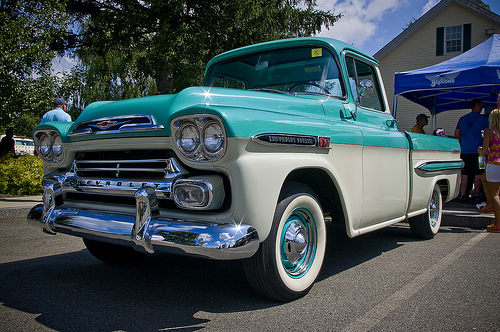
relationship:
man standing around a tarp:
[411, 113, 430, 135] [430, 70, 482, 102]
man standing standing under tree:
[41, 99, 72, 123] [64, 1, 344, 93]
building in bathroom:
[371, 2, 498, 122] [444, 26, 471, 51]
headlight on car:
[175, 116, 225, 158] [27, 37, 462, 299]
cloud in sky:
[325, 5, 357, 35] [284, 2, 479, 67]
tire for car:
[254, 194, 386, 272] [45, 56, 376, 240]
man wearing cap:
[43, 106, 71, 134] [56, 94, 69, 104]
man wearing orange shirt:
[413, 112, 430, 135] [411, 123, 423, 133]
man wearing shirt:
[450, 95, 487, 210] [457, 110, 489, 155]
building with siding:
[371, 2, 499, 149] [368, 1, 492, 137]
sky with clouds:
[366, 1, 431, 56] [313, 4, 430, 46]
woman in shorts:
[476, 106, 498, 231] [482, 159, 499, 184]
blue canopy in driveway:
[399, 22, 499, 106] [3, 189, 497, 330]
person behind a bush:
[3, 122, 25, 169] [4, 159, 43, 199]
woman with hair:
[476, 106, 498, 231] [486, 108, 497, 131]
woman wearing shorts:
[476, 106, 498, 231] [481, 150, 498, 187]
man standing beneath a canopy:
[411, 113, 430, 135] [389, 34, 496, 129]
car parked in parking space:
[27, 37, 462, 299] [3, 211, 498, 330]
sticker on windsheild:
[307, 45, 327, 60] [199, 55, 322, 92]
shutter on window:
[432, 25, 444, 55] [444, 25, 463, 51]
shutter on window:
[462, 20, 472, 52] [444, 25, 463, 51]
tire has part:
[254, 194, 329, 301] [262, 249, 276, 269]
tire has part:
[254, 194, 329, 301] [273, 222, 287, 256]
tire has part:
[254, 194, 329, 301] [313, 244, 323, 258]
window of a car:
[203, 39, 344, 100] [27, 37, 462, 299]